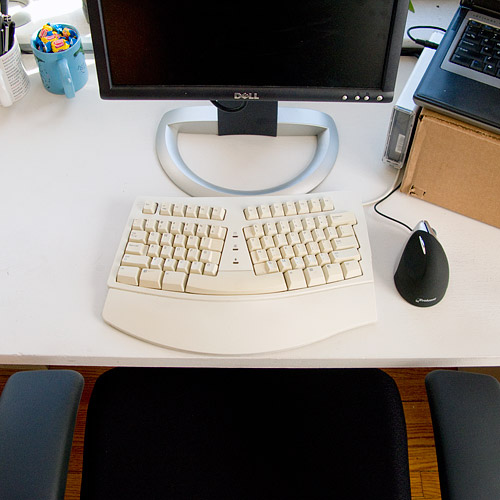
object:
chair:
[0, 367, 499, 498]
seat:
[84, 366, 411, 500]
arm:
[423, 370, 498, 498]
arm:
[1, 368, 85, 499]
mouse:
[393, 229, 450, 308]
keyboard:
[116, 197, 363, 296]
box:
[399, 107, 499, 230]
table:
[0, 0, 499, 371]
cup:
[30, 23, 90, 98]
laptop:
[412, 0, 500, 138]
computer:
[85, 0, 412, 202]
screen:
[98, 0, 401, 89]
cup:
[0, 33, 32, 109]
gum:
[31, 22, 77, 55]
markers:
[0, 14, 15, 58]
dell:
[234, 92, 260, 100]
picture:
[0, 0, 500, 497]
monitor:
[83, 0, 410, 105]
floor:
[0, 364, 458, 497]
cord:
[372, 182, 413, 231]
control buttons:
[342, 94, 384, 102]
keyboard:
[449, 19, 500, 81]